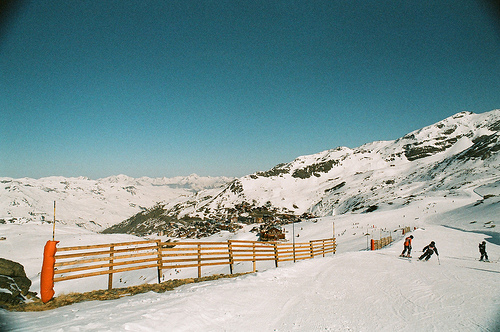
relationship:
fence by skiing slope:
[103, 230, 280, 272] [333, 198, 440, 258]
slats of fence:
[33, 214, 381, 296] [48, 232, 336, 307]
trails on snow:
[387, 239, 499, 281] [5, 92, 493, 328]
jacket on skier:
[400, 237, 413, 250] [389, 224, 419, 262]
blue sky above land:
[94, 69, 213, 154] [67, 148, 462, 295]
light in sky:
[9, 76, 258, 176] [6, 1, 499, 180]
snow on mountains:
[302, 260, 375, 304] [231, 108, 487, 197]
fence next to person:
[28, 224, 349, 285] [472, 237, 491, 261]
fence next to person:
[28, 224, 349, 285] [418, 237, 441, 264]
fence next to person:
[28, 224, 349, 285] [396, 229, 414, 260]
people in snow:
[397, 230, 495, 263] [275, 280, 497, 330]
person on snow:
[478, 240, 490, 262] [5, 92, 493, 328]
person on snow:
[418, 240, 440, 262] [5, 92, 493, 328]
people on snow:
[401, 234, 415, 257] [5, 92, 493, 328]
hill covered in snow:
[0, 108, 500, 332] [5, 92, 493, 328]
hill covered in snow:
[0, 108, 500, 332] [348, 161, 432, 199]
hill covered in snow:
[0, 108, 500, 332] [265, 179, 290, 201]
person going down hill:
[418, 240, 440, 262] [0, 108, 500, 330]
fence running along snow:
[36, 232, 374, 282] [58, 268, 445, 328]